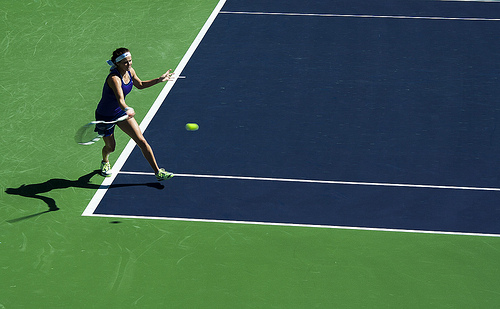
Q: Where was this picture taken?
A: At a tennis court.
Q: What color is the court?
A: Blue and green.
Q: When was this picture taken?
A: During a tennis game.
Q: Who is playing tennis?
A: A woman.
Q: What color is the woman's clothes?
A: Blue.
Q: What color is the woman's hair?
A: Brown.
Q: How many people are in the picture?
A: One.